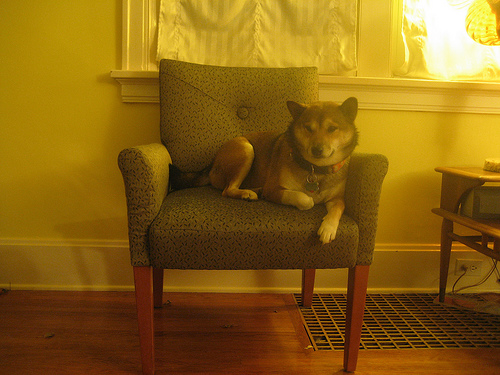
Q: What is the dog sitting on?
A: A chair.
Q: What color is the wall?
A: Yellow.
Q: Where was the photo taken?
A: In a house.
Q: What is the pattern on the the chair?
A: Dots.